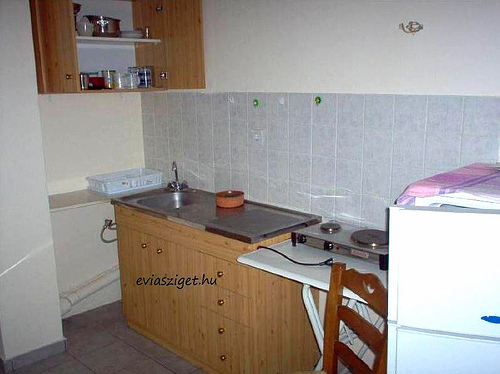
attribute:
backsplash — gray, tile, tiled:
[148, 88, 459, 209]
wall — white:
[204, 5, 489, 112]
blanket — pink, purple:
[413, 157, 500, 199]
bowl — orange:
[218, 183, 262, 219]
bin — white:
[90, 157, 167, 204]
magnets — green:
[247, 94, 332, 107]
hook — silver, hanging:
[383, 19, 435, 45]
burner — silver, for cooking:
[310, 217, 401, 266]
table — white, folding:
[266, 221, 398, 303]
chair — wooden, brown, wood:
[310, 251, 384, 372]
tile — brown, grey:
[57, 307, 148, 371]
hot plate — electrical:
[308, 221, 394, 266]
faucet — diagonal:
[160, 166, 292, 230]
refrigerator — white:
[387, 170, 500, 363]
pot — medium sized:
[94, 16, 129, 45]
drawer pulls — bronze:
[138, 243, 167, 261]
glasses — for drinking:
[141, 29, 154, 35]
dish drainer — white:
[110, 162, 173, 199]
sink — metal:
[141, 175, 205, 221]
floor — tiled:
[67, 292, 147, 372]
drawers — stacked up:
[198, 256, 247, 363]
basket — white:
[99, 159, 165, 196]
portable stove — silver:
[310, 212, 393, 264]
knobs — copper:
[216, 267, 226, 366]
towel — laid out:
[437, 149, 498, 195]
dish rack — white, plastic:
[92, 163, 167, 195]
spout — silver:
[174, 159, 186, 181]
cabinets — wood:
[109, 204, 322, 368]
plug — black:
[307, 260, 336, 273]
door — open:
[395, 211, 493, 368]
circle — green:
[315, 94, 326, 109]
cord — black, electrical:
[250, 244, 324, 287]